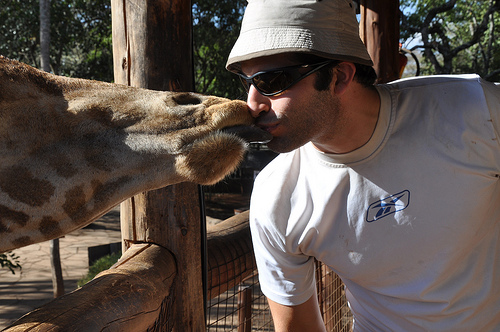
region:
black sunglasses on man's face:
[228, 56, 330, 98]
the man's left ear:
[331, 61, 357, 100]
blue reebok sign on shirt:
[362, 188, 427, 223]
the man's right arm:
[260, 188, 318, 330]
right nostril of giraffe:
[168, 89, 199, 110]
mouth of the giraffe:
[205, 111, 270, 184]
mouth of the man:
[258, 117, 284, 132]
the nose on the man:
[244, 86, 272, 113]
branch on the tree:
[451, 0, 498, 72]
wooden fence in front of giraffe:
[3, 237, 176, 329]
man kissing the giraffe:
[0, 0, 489, 323]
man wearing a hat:
[220, 4, 392, 92]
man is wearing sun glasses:
[226, 51, 334, 106]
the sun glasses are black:
[226, 48, 327, 97]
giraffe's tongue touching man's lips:
[222, 121, 291, 154]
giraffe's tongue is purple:
[212, 116, 269, 151]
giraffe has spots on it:
[0, 111, 179, 263]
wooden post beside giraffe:
[1, 0, 266, 330]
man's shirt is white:
[205, 61, 498, 328]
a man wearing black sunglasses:
[203, 46, 373, 161]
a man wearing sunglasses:
[227, 46, 344, 113]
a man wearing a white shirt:
[224, 49, 498, 291]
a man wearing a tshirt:
[213, 30, 448, 318]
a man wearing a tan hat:
[212, 0, 368, 174]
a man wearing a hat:
[205, 0, 398, 213]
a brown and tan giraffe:
[8, 50, 268, 259]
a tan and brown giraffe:
[7, 53, 281, 255]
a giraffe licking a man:
[21, 35, 361, 274]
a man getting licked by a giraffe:
[159, 42, 455, 304]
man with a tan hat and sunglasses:
[224, 1, 494, 326]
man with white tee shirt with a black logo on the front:
[224, 2, 495, 325]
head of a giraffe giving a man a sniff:
[4, 52, 251, 253]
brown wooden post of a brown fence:
[103, 2, 214, 327]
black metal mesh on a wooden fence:
[200, 215, 360, 329]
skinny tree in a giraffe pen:
[24, 3, 71, 299]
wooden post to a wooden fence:
[359, 0, 401, 79]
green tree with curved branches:
[397, 2, 498, 78]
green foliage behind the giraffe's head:
[0, 2, 109, 77]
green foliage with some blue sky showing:
[186, 2, 243, 92]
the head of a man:
[220, 9, 399, 178]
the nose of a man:
[228, 80, 283, 129]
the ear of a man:
[321, 43, 376, 98]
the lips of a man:
[241, 101, 290, 156]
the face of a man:
[234, 40, 310, 171]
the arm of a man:
[256, 93, 413, 325]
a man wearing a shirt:
[213, 75, 450, 275]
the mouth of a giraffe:
[22, 15, 332, 234]